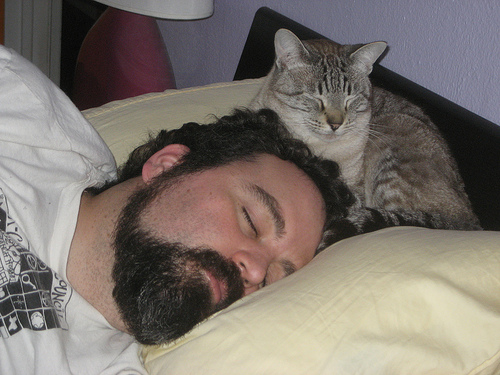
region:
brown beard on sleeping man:
[117, 220, 227, 325]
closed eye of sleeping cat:
[308, 82, 325, 110]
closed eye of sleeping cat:
[345, 86, 376, 114]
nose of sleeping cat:
[310, 108, 350, 138]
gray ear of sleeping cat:
[271, 23, 306, 67]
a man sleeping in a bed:
[25, 126, 340, 362]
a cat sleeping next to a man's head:
[263, 14, 468, 236]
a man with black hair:
[126, 112, 292, 193]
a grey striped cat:
[264, 30, 424, 213]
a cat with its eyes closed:
[290, 65, 372, 137]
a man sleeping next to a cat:
[185, 55, 462, 250]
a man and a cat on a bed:
[93, 24, 441, 341]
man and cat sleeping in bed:
[0, 27, 483, 372]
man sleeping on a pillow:
[0, 41, 367, 373]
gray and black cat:
[245, 27, 484, 237]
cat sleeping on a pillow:
[241, 27, 485, 233]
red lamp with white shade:
[69, 0, 218, 109]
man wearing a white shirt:
[0, 40, 356, 373]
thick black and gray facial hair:
[110, 170, 245, 345]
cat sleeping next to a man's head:
[110, 25, 480, 347]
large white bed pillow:
[80, 71, 495, 371]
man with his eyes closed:
[1, 43, 362, 374]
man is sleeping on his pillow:
[1, 45, 334, 374]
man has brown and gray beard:
[112, 164, 242, 343]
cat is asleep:
[243, 28, 480, 256]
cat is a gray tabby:
[246, 30, 481, 252]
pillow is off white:
[81, 76, 499, 372]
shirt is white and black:
[0, 43, 150, 373]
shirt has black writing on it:
[3, 198, 70, 328]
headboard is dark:
[229, 8, 499, 233]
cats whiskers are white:
[292, 120, 389, 148]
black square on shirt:
[42, 308, 57, 327]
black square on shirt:
[27, 307, 46, 329]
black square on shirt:
[18, 253, 30, 273]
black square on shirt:
[12, 307, 28, 327]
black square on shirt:
[2, 311, 18, 332]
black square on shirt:
[0, 297, 16, 313]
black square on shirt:
[10, 293, 25, 308]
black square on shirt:
[23, 290, 40, 310]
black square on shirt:
[18, 271, 36, 291]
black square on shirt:
[38, 270, 50, 289]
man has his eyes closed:
[0, 41, 357, 373]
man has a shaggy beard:
[107, 169, 254, 346]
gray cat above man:
[245, 26, 483, 232]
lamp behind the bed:
[68, 0, 213, 110]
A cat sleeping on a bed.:
[281, 30, 456, 231]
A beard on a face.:
[124, 165, 249, 330]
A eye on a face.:
[236, 204, 285, 254]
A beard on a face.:
[104, 167, 240, 371]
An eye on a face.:
[235, 201, 270, 258]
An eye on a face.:
[306, 82, 330, 117]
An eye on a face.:
[338, 90, 368, 120]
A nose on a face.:
[233, 232, 266, 287]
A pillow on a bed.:
[113, 214, 438, 358]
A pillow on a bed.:
[173, 64, 292, 146]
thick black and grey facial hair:
[106, 170, 243, 347]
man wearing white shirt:
[0, 43, 355, 374]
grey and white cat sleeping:
[247, 26, 482, 236]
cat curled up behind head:
[247, 25, 483, 232]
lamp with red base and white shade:
[71, 0, 213, 112]